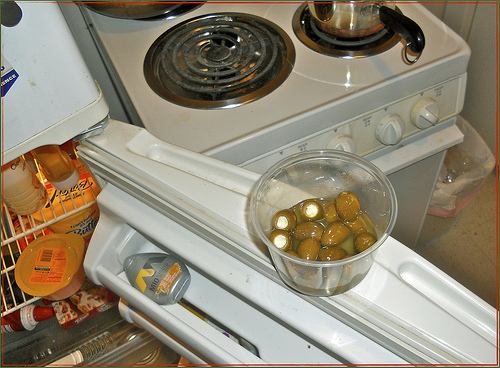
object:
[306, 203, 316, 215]
cheese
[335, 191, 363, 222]
olive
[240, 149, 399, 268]
round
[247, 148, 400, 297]
container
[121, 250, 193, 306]
drink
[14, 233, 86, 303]
ham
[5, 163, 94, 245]
shelf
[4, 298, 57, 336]
whip cream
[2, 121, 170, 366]
in fridge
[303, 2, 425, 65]
pot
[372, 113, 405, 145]
white button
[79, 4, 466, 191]
white stove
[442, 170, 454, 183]
plastic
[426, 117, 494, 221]
bag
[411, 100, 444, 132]
knob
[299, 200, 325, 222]
stuffed olives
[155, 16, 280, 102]
burner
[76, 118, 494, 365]
door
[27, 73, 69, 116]
white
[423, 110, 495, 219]
trash can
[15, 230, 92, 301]
bologna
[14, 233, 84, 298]
package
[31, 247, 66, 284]
orange ingredient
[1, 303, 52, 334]
whipped cream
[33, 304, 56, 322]
long red lid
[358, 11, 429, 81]
pan handle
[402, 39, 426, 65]
silver ring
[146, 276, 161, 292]
mio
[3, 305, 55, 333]
can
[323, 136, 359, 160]
white handle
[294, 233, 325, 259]
olives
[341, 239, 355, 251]
liquid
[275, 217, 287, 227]
white cheese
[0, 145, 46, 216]
sweetner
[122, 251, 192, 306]
silver bottle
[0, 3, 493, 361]
fridge